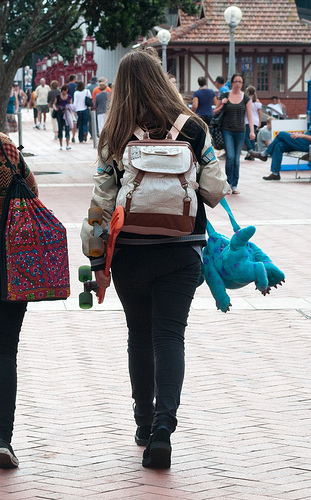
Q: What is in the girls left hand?
A: Skateboard.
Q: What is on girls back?
A: Backpack.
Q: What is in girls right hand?
A: Monster purse.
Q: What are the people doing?
A: Walking.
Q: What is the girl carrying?
A: A skateboard.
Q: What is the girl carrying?
A: Fuzzy purse.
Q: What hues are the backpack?
A: Brown and beige.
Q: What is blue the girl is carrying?
A: Blue stuffed animal.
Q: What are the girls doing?
A: Walking.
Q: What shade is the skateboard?
A: Orange.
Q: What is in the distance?
A: Many people.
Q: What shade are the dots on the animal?
A: Purple.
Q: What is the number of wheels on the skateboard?
A: Four.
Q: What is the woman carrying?
A: Bags and skateboards.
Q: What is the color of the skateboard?
A: Orange and green.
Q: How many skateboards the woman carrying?
A: One.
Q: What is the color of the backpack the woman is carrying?
A: Brown and white.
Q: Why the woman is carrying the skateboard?
A: To play with later.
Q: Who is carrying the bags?
A: A woman.